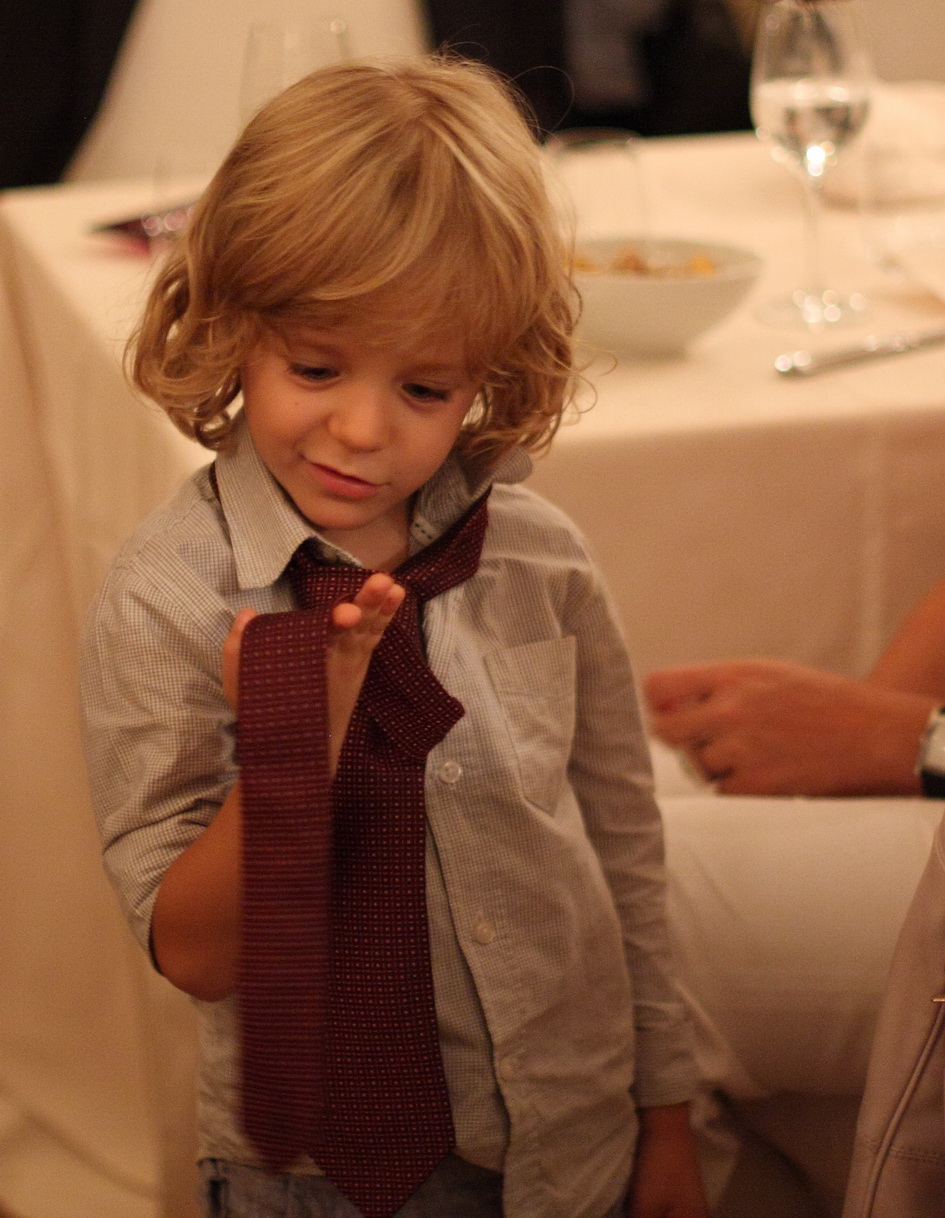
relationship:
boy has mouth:
[76, 22, 713, 1218] [302, 445, 391, 515]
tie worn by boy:
[203, 467, 510, 1210] [76, 22, 713, 1218]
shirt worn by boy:
[79, 405, 698, 1218] [76, 22, 713, 1218]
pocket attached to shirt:
[478, 627, 598, 821] [88, 408, 744, 1210]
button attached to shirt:
[429, 754, 466, 791] [88, 408, 744, 1210]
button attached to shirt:
[457, 915, 501, 949] [88, 408, 744, 1210]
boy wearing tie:
[75, 63, 771, 1215] [220, 498, 517, 1214]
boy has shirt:
[75, 63, 771, 1215] [88, 408, 744, 1210]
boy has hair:
[75, 63, 771, 1215] [134, 41, 573, 461]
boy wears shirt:
[75, 63, 771, 1215] [88, 408, 744, 1210]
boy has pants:
[76, 22, 713, 1218] [620, 730, 906, 1104]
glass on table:
[728, 16, 863, 439] [2, 101, 910, 664]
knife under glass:
[755, 283, 936, 413] [750, 0, 869, 335]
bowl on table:
[571, 206, 808, 473] [0, 94, 912, 819]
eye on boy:
[280, 355, 348, 385] [76, 22, 713, 1218]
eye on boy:
[402, 363, 463, 426] [76, 22, 713, 1218]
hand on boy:
[213, 574, 432, 745] [76, 22, 713, 1218]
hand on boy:
[618, 1083, 727, 1210] [76, 22, 713, 1218]